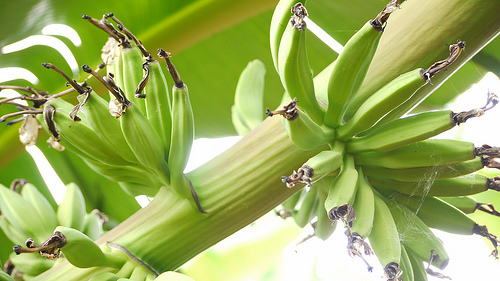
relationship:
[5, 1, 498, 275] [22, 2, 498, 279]
plant has limb